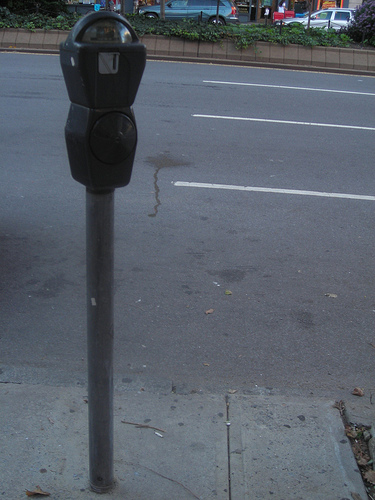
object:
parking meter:
[56, 8, 146, 190]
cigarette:
[152, 427, 165, 439]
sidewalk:
[0, 383, 369, 499]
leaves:
[364, 467, 375, 487]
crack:
[147, 168, 164, 220]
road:
[3, 49, 373, 394]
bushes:
[2, 0, 32, 17]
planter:
[1, 26, 372, 73]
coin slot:
[111, 50, 118, 74]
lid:
[87, 109, 137, 166]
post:
[83, 185, 114, 494]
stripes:
[186, 105, 373, 131]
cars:
[141, 0, 242, 29]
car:
[279, 7, 355, 32]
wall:
[1, 29, 373, 75]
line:
[168, 176, 374, 205]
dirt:
[346, 423, 373, 496]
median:
[0, 23, 375, 75]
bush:
[345, 0, 374, 49]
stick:
[119, 417, 165, 434]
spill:
[218, 266, 246, 285]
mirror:
[309, 13, 318, 21]